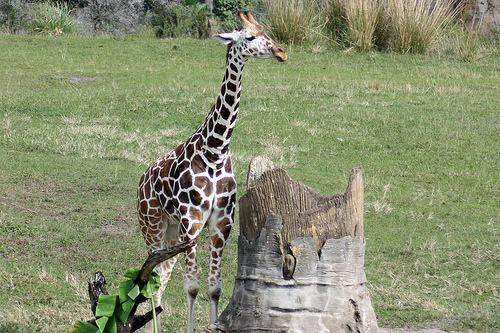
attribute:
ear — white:
[211, 30, 243, 47]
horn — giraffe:
[232, 4, 257, 29]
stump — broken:
[240, 152, 392, 322]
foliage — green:
[7, 0, 85, 36]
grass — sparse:
[358, 83, 498, 224]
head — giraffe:
[212, 12, 289, 63]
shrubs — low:
[2, 0, 488, 70]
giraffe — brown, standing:
[132, 5, 287, 330]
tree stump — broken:
[211, 153, 382, 330]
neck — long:
[193, 54, 244, 151]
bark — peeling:
[242, 163, 360, 315]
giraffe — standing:
[103, 10, 288, 331]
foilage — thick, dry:
[270, 7, 497, 77]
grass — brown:
[371, 100, 451, 157]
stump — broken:
[251, 134, 355, 276]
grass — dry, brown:
[349, 82, 439, 190]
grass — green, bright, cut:
[1, 29, 495, 331]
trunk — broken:
[221, 140, 415, 328]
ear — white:
[198, 23, 256, 68]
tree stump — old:
[233, 157, 371, 330]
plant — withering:
[69, 242, 183, 325]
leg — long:
[207, 225, 225, 330]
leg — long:
[179, 232, 196, 330]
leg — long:
[155, 227, 174, 329]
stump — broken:
[205, 152, 377, 332]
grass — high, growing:
[18, 36, 477, 311]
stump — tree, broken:
[216, 158, 377, 331]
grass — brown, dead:
[72, 112, 138, 173]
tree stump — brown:
[207, 160, 396, 332]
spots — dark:
[174, 154, 219, 176]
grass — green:
[22, 205, 132, 267]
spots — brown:
[184, 71, 413, 102]